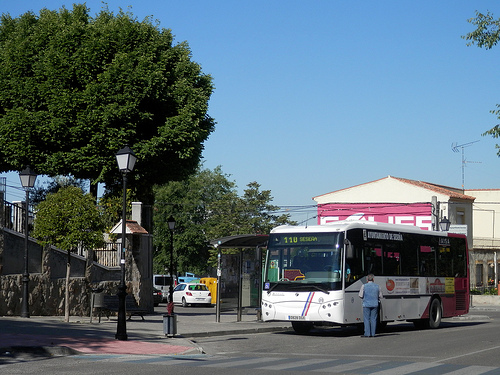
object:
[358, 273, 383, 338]
person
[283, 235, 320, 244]
read out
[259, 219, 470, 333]
bus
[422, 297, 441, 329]
tire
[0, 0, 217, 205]
tree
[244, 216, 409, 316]
bus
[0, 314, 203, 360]
sidewalk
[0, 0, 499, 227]
blue sky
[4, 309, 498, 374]
road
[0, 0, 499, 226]
cloud